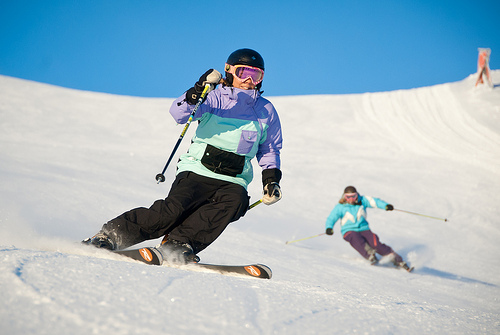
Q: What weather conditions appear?
A: It is clear.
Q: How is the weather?
A: It is clear.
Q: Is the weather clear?
A: Yes, it is clear.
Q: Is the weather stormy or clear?
A: It is clear.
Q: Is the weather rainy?
A: No, it is clear.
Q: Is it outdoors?
A: Yes, it is outdoors.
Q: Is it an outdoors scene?
A: Yes, it is outdoors.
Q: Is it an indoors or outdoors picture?
A: It is outdoors.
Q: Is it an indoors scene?
A: No, it is outdoors.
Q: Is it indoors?
A: No, it is outdoors.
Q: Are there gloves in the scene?
A: Yes, there are gloves.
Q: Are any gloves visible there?
A: Yes, there are gloves.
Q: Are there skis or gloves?
A: Yes, there are gloves.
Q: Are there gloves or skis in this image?
A: Yes, there are gloves.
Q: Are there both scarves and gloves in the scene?
A: No, there are gloves but no scarves.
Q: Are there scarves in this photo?
A: No, there are no scarves.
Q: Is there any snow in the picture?
A: Yes, there is snow.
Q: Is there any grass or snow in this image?
A: Yes, there is snow.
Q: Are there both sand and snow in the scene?
A: No, there is snow but no sand.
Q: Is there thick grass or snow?
A: Yes, there is thick snow.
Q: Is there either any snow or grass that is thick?
A: Yes, the snow is thick.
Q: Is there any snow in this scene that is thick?
A: Yes, there is thick snow.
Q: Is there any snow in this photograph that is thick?
A: Yes, there is snow that is thick.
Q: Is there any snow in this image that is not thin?
A: Yes, there is thick snow.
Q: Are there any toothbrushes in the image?
A: No, there are no toothbrushes.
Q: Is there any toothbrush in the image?
A: No, there are no toothbrushes.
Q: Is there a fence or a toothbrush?
A: No, there are no toothbrushes or fences.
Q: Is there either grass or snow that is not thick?
A: No, there is snow but it is thick.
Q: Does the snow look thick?
A: Yes, the snow is thick.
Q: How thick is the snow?
A: The snow is thick.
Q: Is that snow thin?
A: No, the snow is thick.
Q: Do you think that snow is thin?
A: No, the snow is thick.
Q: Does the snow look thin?
A: No, the snow is thick.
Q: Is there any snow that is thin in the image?
A: No, there is snow but it is thick.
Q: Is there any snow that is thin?
A: No, there is snow but it is thick.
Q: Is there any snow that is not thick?
A: No, there is snow but it is thick.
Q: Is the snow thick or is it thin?
A: The snow is thick.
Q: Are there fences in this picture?
A: No, there are no fences.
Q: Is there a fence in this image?
A: No, there are no fences.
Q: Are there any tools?
A: No, there are no tools.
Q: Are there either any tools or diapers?
A: No, there are no tools or diapers.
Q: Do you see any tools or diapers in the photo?
A: No, there are no tools or diapers.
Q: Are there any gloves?
A: Yes, there are gloves.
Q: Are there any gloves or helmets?
A: Yes, there are gloves.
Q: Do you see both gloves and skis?
A: Yes, there are both gloves and skis.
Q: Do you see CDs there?
A: No, there are no cds.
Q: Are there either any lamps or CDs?
A: No, there are no CDs or lamps.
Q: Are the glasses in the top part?
A: Yes, the glasses are in the top of the image.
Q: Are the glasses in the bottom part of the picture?
A: No, the glasses are in the top of the image.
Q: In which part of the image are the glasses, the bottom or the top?
A: The glasses are in the top of the image.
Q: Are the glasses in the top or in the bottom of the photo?
A: The glasses are in the top of the image.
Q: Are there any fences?
A: No, there are no fences.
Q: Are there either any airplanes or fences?
A: No, there are no fences or airplanes.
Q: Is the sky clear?
A: Yes, the sky is clear.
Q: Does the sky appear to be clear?
A: Yes, the sky is clear.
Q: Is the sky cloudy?
A: No, the sky is clear.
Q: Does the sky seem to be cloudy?
A: No, the sky is clear.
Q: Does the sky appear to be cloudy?
A: No, the sky is clear.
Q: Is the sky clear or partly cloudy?
A: The sky is clear.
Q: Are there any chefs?
A: No, there are no chefs.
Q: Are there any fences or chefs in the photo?
A: No, there are no chefs or fences.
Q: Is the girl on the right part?
A: Yes, the girl is on the right of the image.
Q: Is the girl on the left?
A: No, the girl is on the right of the image.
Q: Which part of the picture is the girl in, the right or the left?
A: The girl is on the right of the image.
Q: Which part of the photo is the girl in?
A: The girl is on the right of the image.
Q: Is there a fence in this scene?
A: No, there are no fences.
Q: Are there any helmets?
A: Yes, there is a helmet.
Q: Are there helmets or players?
A: Yes, there is a helmet.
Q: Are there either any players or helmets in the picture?
A: Yes, there is a helmet.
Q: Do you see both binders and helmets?
A: No, there is a helmet but no binders.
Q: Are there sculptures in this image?
A: No, there are no sculptures.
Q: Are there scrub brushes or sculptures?
A: No, there are no sculptures or scrub brushes.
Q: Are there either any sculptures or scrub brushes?
A: No, there are no sculptures or scrub brushes.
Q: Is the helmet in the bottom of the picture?
A: No, the helmet is in the top of the image.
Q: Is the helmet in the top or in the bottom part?
A: The helmet is in the top of the image.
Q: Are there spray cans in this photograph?
A: No, there are no spray cans.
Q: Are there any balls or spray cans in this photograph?
A: No, there are no spray cans or balls.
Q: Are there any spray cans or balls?
A: No, there are no spray cans or balls.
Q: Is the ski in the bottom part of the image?
A: Yes, the ski is in the bottom of the image.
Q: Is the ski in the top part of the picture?
A: No, the ski is in the bottom of the image.